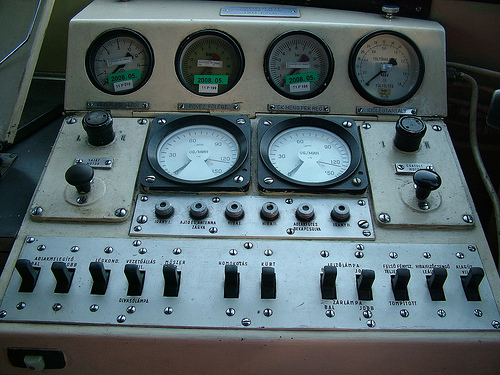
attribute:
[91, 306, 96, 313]
bolt — silver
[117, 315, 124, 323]
bolt — silver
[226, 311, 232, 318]
bolt — silver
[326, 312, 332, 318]
bolt — silver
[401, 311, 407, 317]
bolt — silver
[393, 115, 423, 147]
knobs — black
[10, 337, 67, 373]
button — white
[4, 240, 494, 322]
panel — silver 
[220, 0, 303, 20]
panel — silver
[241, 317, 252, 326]
screw — silver 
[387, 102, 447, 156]
knob — large 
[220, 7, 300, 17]
plate — metal 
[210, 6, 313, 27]
plate — small 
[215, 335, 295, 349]
specks — black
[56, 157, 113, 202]
knob — screw shaped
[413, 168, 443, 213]
button — black , smooth 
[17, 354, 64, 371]
button — small, white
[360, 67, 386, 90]
needle — black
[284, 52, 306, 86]
needle — black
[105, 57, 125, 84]
needle — black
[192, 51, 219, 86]
needle — black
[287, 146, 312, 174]
needle — black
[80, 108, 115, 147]
knob — large, black